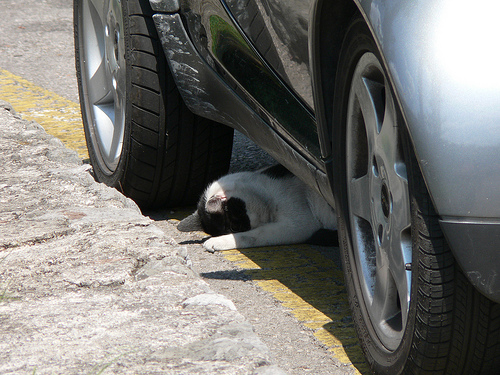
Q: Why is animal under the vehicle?
A: Sleeping.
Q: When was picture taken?
A: Daytime.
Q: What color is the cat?
A: Black and white.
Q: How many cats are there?
A: One.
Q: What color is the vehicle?
A: Silver.